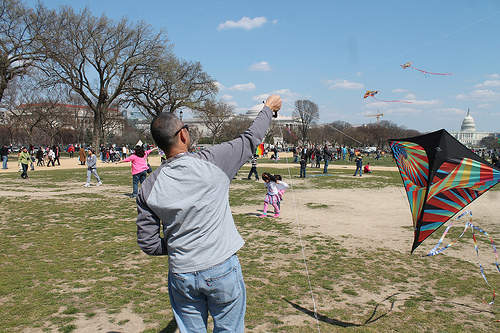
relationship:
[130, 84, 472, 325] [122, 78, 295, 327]
man a kite man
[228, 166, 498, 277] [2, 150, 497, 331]
tan on ground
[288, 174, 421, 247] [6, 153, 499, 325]
dirt in grass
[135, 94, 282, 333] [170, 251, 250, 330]
man wearing jeans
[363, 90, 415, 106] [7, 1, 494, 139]
kite are in sky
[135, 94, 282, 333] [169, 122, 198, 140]
man wearing specks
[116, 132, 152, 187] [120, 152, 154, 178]
lady wearing t-shirt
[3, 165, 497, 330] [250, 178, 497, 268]
grass with sand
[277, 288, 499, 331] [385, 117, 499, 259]
shadow from kite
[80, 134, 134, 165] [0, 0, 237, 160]
people standing under tall trees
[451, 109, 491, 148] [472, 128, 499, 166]
building behind tree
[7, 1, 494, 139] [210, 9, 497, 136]
sky has clouds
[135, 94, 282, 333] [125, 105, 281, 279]
man wearing shirt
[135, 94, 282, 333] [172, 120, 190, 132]
man wearing sunglasses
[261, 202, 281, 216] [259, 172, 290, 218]
tights on child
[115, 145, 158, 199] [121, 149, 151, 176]
lady wearing sweater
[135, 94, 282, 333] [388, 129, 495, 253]
man flying a kite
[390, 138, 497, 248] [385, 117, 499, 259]
design on kite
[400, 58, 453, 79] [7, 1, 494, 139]
kite in sky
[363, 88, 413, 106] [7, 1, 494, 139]
kite in sky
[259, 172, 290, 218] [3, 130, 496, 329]
child in park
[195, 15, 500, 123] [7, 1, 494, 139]
clouds in sky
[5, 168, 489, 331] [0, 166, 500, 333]
spots in grass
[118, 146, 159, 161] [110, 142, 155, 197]
arms on woman